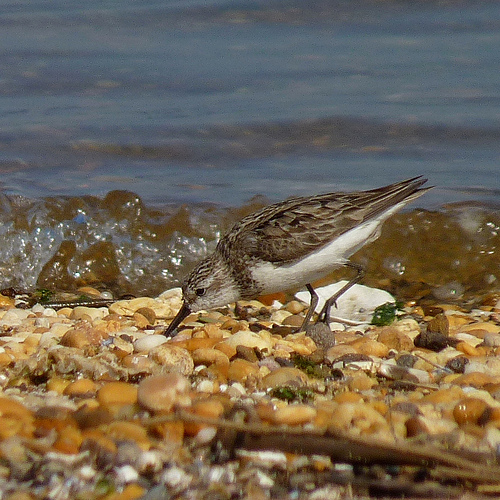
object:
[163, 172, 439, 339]
bird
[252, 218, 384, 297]
underbelly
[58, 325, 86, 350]
pebbles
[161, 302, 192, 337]
beak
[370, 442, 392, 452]
twigs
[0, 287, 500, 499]
ground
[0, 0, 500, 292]
water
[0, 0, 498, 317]
background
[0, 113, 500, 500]
beach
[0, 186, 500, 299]
wave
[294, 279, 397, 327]
seashell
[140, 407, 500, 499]
stick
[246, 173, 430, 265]
wing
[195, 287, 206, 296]
eye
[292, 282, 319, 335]
feet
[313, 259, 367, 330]
foot